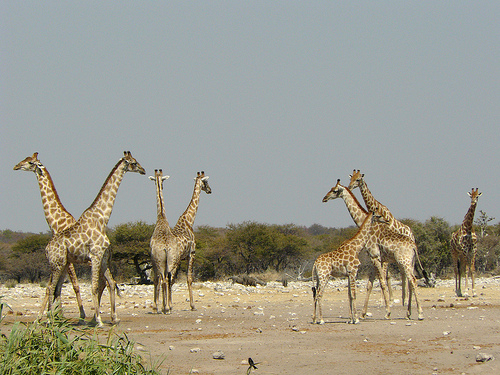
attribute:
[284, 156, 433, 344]
creatures — beautiful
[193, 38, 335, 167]
sky — blue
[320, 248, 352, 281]
spots — brown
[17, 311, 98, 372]
bush — green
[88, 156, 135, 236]
neck — long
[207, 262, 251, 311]
rocks — silver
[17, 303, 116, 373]
foliage — wild, green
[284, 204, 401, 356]
giraffe — young, wild